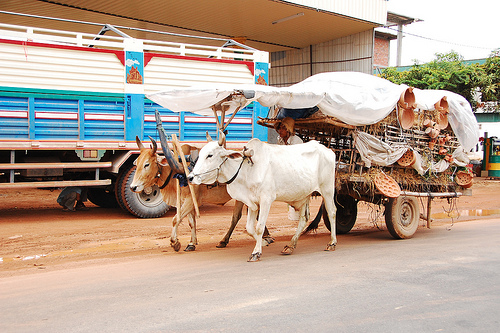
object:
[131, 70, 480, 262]
cart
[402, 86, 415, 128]
pottery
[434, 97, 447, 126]
pottery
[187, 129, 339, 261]
cow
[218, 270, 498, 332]
road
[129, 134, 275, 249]
cow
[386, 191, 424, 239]
wheel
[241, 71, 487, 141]
cloth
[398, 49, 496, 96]
trees